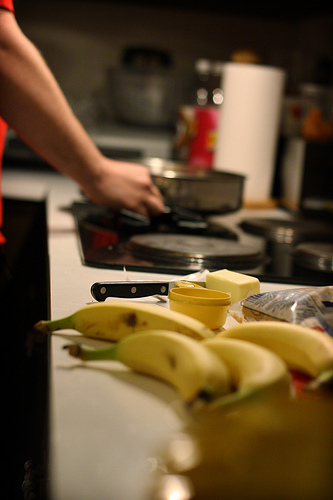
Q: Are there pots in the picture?
A: Yes, there is a pot.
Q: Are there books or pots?
A: Yes, there is a pot.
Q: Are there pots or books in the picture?
A: Yes, there is a pot.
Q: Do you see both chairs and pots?
A: No, there is a pot but no chairs.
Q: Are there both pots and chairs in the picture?
A: No, there is a pot but no chairs.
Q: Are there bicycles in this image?
A: No, there are no bicycles.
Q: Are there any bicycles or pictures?
A: No, there are no bicycles or pictures.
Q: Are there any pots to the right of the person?
A: Yes, there is a pot to the right of the person.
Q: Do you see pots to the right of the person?
A: Yes, there is a pot to the right of the person.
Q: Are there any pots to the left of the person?
A: No, the pot is to the right of the person.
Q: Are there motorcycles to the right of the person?
A: No, there is a pot to the right of the person.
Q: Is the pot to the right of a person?
A: Yes, the pot is to the right of a person.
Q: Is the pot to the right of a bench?
A: No, the pot is to the right of a person.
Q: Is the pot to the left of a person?
A: No, the pot is to the right of a person.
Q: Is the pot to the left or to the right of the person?
A: The pot is to the right of the person.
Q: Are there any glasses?
A: No, there are no glasses.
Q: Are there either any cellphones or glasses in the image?
A: No, there are no glasses or cellphones.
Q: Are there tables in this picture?
A: Yes, there is a table.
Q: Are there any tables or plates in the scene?
A: Yes, there is a table.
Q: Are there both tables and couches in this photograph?
A: No, there is a table but no couches.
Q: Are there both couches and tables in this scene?
A: No, there is a table but no couches.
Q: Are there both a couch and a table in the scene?
A: No, there is a table but no couches.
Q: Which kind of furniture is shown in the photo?
A: The furniture is a table.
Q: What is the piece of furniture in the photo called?
A: The piece of furniture is a table.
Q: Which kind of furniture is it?
A: The piece of furniture is a table.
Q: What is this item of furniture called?
A: This is a table.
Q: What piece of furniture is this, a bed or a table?
A: This is a table.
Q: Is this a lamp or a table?
A: This is a table.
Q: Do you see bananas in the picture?
A: Yes, there is a banana.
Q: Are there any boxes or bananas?
A: Yes, there is a banana.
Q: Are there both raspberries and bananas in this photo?
A: No, there is a banana but no raspberries.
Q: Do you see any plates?
A: No, there are no plates.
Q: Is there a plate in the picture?
A: No, there are no plates.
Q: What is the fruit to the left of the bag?
A: The fruit is a banana.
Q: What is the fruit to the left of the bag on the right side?
A: The fruit is a banana.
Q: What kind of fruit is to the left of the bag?
A: The fruit is a banana.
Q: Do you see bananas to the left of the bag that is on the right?
A: Yes, there is a banana to the left of the bag.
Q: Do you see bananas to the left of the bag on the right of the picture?
A: Yes, there is a banana to the left of the bag.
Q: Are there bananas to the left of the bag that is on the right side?
A: Yes, there is a banana to the left of the bag.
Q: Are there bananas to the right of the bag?
A: No, the banana is to the left of the bag.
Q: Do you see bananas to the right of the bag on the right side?
A: No, the banana is to the left of the bag.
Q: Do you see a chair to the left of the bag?
A: No, there is a banana to the left of the bag.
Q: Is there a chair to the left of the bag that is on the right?
A: No, there is a banana to the left of the bag.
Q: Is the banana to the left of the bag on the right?
A: Yes, the banana is to the left of the bag.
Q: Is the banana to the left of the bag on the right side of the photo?
A: Yes, the banana is to the left of the bag.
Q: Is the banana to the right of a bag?
A: No, the banana is to the left of a bag.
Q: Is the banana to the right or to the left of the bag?
A: The banana is to the left of the bag.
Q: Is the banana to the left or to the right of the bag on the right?
A: The banana is to the left of the bag.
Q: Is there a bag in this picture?
A: Yes, there is a bag.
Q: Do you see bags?
A: Yes, there is a bag.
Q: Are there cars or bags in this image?
A: Yes, there is a bag.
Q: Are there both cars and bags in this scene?
A: No, there is a bag but no cars.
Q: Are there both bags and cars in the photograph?
A: No, there is a bag but no cars.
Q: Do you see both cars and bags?
A: No, there is a bag but no cars.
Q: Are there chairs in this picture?
A: No, there are no chairs.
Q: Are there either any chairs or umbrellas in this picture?
A: No, there are no chairs or umbrellas.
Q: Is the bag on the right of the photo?
A: Yes, the bag is on the right of the image.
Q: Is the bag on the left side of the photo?
A: No, the bag is on the right of the image.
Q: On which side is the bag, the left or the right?
A: The bag is on the right of the image.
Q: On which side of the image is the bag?
A: The bag is on the right of the image.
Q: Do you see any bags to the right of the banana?
A: Yes, there is a bag to the right of the banana.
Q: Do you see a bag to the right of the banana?
A: Yes, there is a bag to the right of the banana.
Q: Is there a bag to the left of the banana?
A: No, the bag is to the right of the banana.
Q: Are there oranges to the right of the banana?
A: No, there is a bag to the right of the banana.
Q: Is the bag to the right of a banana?
A: Yes, the bag is to the right of a banana.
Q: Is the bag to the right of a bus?
A: No, the bag is to the right of a banana.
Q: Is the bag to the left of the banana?
A: No, the bag is to the right of the banana.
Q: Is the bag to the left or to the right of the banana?
A: The bag is to the right of the banana.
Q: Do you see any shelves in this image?
A: No, there are no shelves.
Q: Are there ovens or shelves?
A: No, there are no shelves or ovens.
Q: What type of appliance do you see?
A: The appliance is a stove.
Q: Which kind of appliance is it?
A: The appliance is a stove.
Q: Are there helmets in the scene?
A: No, there are no helmets.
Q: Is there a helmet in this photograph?
A: No, there are no helmets.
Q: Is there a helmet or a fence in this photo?
A: No, there are no helmets or fences.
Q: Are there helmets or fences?
A: No, there are no helmets or fences.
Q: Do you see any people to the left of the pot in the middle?
A: Yes, there is a person to the left of the pot.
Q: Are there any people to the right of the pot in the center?
A: No, the person is to the left of the pot.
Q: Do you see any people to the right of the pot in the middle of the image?
A: No, the person is to the left of the pot.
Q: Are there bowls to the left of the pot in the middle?
A: No, there is a person to the left of the pot.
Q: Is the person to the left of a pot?
A: Yes, the person is to the left of a pot.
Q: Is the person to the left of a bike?
A: No, the person is to the left of a pot.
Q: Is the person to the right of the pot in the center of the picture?
A: No, the person is to the left of the pot.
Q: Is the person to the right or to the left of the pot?
A: The person is to the left of the pot.